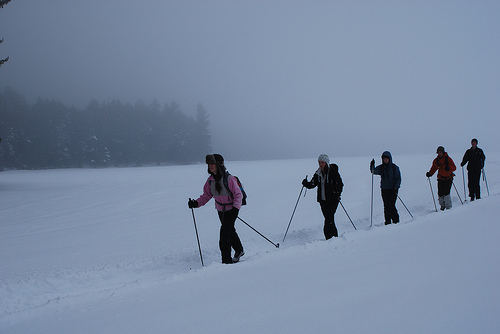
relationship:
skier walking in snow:
[188, 153, 248, 265] [0, 152, 499, 334]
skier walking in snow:
[303, 153, 344, 240] [0, 152, 499, 334]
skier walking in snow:
[370, 151, 402, 226] [0, 152, 499, 334]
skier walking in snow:
[426, 146, 457, 211] [0, 152, 499, 334]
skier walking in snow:
[460, 137, 486, 201] [0, 152, 499, 334]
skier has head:
[303, 153, 344, 240] [317, 153, 330, 171]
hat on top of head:
[317, 154, 330, 167] [317, 153, 330, 171]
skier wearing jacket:
[188, 153, 248, 265] [195, 174, 244, 212]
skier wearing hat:
[188, 153, 248, 265] [205, 153, 224, 165]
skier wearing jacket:
[426, 146, 457, 211] [428, 153, 457, 178]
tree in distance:
[82, 98, 112, 167] [1, 1, 500, 170]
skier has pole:
[188, 153, 248, 265] [188, 198, 206, 266]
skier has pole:
[188, 153, 248, 265] [237, 215, 281, 247]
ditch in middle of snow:
[4, 184, 497, 324] [0, 152, 499, 334]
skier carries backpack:
[188, 153, 248, 265] [232, 174, 247, 205]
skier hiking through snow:
[188, 153, 248, 265] [0, 152, 499, 334]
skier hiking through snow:
[303, 153, 344, 240] [0, 152, 499, 334]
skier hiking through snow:
[370, 151, 402, 226] [0, 152, 499, 334]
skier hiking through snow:
[426, 146, 457, 211] [0, 152, 499, 334]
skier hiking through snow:
[460, 137, 486, 201] [0, 152, 499, 334]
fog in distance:
[0, 0, 499, 170] [1, 1, 500, 170]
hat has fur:
[205, 153, 224, 165] [205, 154, 217, 164]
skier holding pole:
[188, 153, 248, 265] [188, 198, 206, 266]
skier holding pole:
[188, 153, 248, 265] [237, 215, 281, 247]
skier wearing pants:
[188, 153, 248, 265] [216, 209, 244, 263]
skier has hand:
[188, 153, 248, 265] [187, 199, 197, 209]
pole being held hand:
[188, 198, 206, 266] [187, 199, 197, 209]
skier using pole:
[188, 153, 248, 265] [188, 198, 206, 266]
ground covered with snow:
[0, 153, 499, 333] [0, 152, 499, 334]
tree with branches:
[82, 98, 112, 167] [105, 145, 110, 162]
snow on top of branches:
[103, 148, 111, 164] [103, 145, 111, 166]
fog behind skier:
[0, 0, 499, 170] [188, 153, 248, 265]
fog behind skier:
[0, 0, 499, 170] [303, 153, 344, 240]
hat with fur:
[205, 153, 224, 165] [205, 154, 217, 164]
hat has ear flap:
[205, 153, 224, 165] [217, 165, 225, 175]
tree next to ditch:
[82, 98, 112, 167] [4, 184, 497, 324]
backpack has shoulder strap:
[232, 174, 247, 205] [222, 173, 234, 198]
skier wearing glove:
[188, 153, 248, 265] [188, 199, 199, 209]